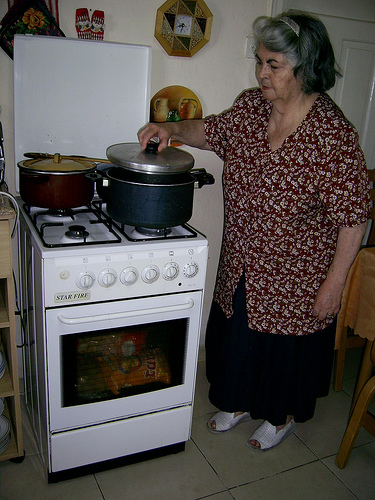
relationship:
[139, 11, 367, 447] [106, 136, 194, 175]
woman holding lid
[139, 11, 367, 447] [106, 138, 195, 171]
woman holding lid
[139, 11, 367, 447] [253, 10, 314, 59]
woman has hair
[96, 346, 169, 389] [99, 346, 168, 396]
bag of potato chips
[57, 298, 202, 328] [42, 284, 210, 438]
handle of door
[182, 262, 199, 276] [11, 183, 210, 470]
knob on stove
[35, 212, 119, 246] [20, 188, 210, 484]
burner on stove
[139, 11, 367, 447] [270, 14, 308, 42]
woman wears a headband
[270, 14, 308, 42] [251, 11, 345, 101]
headband worn in her hair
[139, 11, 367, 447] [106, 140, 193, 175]
woman holding lid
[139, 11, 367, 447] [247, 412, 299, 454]
woman wears a white shoe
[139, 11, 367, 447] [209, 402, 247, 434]
woman wears a white right shoe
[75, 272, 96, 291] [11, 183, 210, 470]
knob of stove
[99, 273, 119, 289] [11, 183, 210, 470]
knob of stove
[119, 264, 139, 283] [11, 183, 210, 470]
knob of stove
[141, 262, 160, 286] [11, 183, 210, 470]
knob of stove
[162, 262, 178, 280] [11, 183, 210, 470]
knob of stove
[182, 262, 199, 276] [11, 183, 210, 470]
knob of stove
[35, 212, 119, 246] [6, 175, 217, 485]
burner on stove